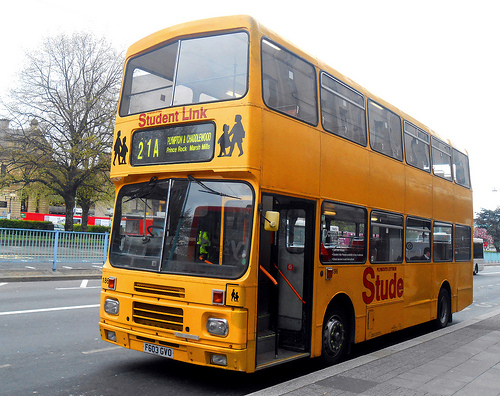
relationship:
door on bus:
[260, 190, 311, 367] [100, 29, 489, 375]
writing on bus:
[355, 256, 435, 306] [100, 29, 489, 375]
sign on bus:
[128, 130, 212, 164] [100, 29, 489, 375]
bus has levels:
[100, 29, 489, 375] [120, 35, 472, 319]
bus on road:
[100, 29, 489, 375] [19, 280, 491, 353]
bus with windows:
[100, 29, 489, 375] [258, 35, 481, 191]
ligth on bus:
[99, 291, 124, 322] [100, 29, 489, 375]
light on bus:
[203, 299, 235, 341] [100, 29, 489, 375]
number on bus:
[132, 138, 154, 168] [100, 29, 489, 375]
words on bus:
[138, 105, 216, 126] [100, 29, 489, 375]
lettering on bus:
[164, 132, 215, 165] [100, 29, 489, 375]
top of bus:
[132, 33, 492, 186] [100, 29, 489, 375]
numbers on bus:
[144, 342, 179, 365] [100, 29, 489, 375]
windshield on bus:
[112, 164, 243, 293] [100, 29, 489, 375]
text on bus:
[164, 132, 215, 165] [100, 29, 489, 375]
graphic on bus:
[109, 132, 141, 190] [100, 29, 489, 375]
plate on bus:
[130, 338, 186, 369] [100, 29, 489, 375]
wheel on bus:
[320, 303, 352, 365] [100, 29, 489, 375]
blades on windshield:
[190, 176, 259, 218] [112, 164, 243, 293]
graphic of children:
[112, 129, 128, 166] [109, 126, 123, 170]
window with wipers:
[112, 164, 243, 293] [92, 181, 262, 302]